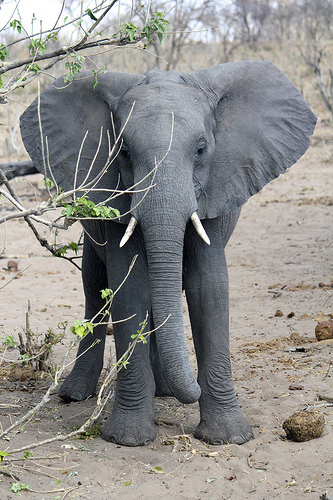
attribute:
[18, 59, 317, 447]
elephant — small, young, african, standing, grey, large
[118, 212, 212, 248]
tusks — white, pointy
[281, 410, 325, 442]
poop — ball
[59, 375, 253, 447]
feet — grey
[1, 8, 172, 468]
leaves — green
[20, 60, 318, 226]
ears — big, large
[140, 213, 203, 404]
trunk — long, huge, powerful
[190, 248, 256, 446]
leg — left front leg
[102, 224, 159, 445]
leg — right front leg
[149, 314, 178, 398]
leg — back left leg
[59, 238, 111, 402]
leg — back right leg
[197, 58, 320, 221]
ear — large, left ear, right ear, big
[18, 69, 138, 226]
ear — large, right ear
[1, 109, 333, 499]
ground — dusty, dirt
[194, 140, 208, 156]
eye — left eye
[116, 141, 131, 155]
eye — right eye